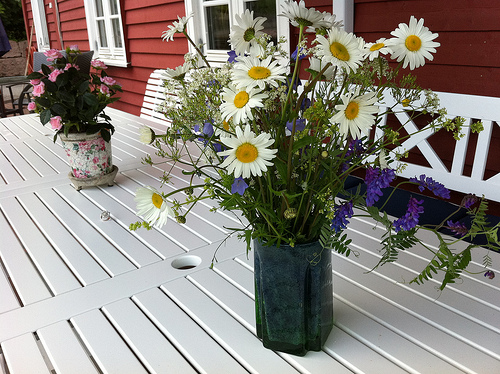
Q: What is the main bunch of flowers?
A: Daisies.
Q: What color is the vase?
A: Blue green.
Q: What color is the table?
A: White.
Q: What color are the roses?
A: Pink.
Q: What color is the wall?
A: Red.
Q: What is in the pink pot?
A: Roses.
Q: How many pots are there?
A: 2.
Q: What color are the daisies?
A: White.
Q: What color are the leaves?
A: Green.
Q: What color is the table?
A: White.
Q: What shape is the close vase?
A: Round.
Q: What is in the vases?
A: Flowers.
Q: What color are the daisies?
A: Yellow and white.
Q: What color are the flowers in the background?
A: Purple.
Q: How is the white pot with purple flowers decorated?
A: With pink flowers.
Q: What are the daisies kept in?
A: Glass vase.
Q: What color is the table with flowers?
A: White.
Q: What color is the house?
A: Red.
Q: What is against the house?
A: A bench.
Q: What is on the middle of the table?
A: A hole.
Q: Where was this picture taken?
A: A porch.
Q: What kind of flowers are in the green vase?
A: Sunflowers.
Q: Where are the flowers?
A: In a vase outside.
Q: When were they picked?
A: Recently.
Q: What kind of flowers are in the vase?
A: Daisies and heather.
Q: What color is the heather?
A: Purple.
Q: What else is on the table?
A: A potted plant.